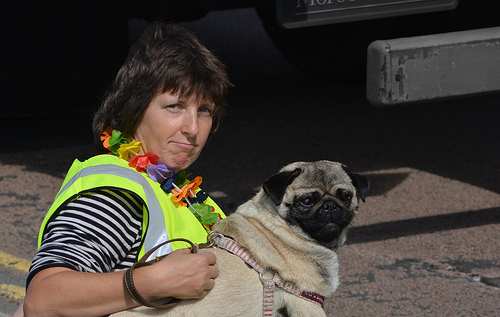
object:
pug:
[108, 159, 370, 316]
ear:
[261, 167, 304, 206]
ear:
[341, 164, 371, 204]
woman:
[22, 21, 227, 316]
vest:
[38, 155, 227, 262]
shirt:
[24, 187, 144, 286]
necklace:
[102, 126, 222, 226]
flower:
[129, 152, 160, 172]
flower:
[144, 164, 172, 183]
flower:
[170, 175, 202, 207]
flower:
[117, 141, 140, 162]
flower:
[107, 129, 131, 157]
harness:
[208, 233, 325, 314]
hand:
[160, 248, 220, 302]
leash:
[124, 237, 198, 311]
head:
[95, 20, 232, 176]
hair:
[90, 24, 234, 139]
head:
[261, 160, 372, 242]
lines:
[0, 249, 34, 273]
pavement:
[2, 118, 499, 317]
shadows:
[344, 206, 499, 245]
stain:
[374, 256, 420, 271]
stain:
[444, 257, 499, 274]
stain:
[2, 191, 40, 201]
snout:
[312, 199, 344, 228]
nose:
[321, 200, 337, 213]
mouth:
[316, 218, 344, 235]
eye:
[163, 102, 184, 113]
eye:
[198, 105, 212, 114]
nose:
[180, 109, 200, 138]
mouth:
[168, 139, 200, 149]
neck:
[108, 135, 182, 181]